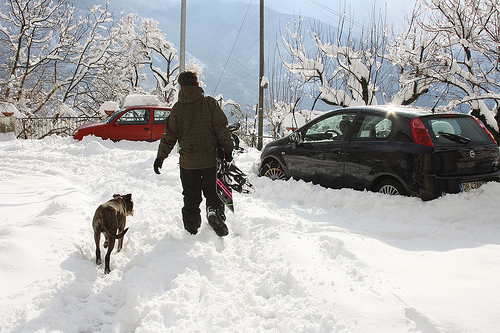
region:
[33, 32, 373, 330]
a person and dog in the snow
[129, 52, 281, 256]
a person holding a snowboard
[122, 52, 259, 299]
a man holding a surfboard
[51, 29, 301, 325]
a man and dog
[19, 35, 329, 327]
a man and dog walking on snow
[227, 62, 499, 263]
a car surround with snow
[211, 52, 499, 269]
snow surrounding a car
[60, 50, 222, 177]
a red car surround in snow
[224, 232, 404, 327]
white snow covering the ground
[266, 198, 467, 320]
snow covering the ground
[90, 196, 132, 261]
back of walking dog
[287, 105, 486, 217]
black car in snow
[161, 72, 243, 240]
man carrying snowboard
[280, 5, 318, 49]
top of mountain on horizon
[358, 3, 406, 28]
blue of daytime sky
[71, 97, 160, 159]
red car in snow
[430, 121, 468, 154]
wiper on back of car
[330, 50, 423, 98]
snow on tree limbs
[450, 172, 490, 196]
license plate on car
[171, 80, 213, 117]
hood on back of coat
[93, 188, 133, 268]
dog walking on snow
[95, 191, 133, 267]
dog has short hair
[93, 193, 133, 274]
dog wagging his tail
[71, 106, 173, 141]
red car parked in snow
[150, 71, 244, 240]
man walking in snow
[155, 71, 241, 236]
man carrying snowboard in snow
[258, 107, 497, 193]
black car parked in snow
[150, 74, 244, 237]
man wearing black pants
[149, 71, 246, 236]
man wearing black boots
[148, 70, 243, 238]
man wearing plaid jacket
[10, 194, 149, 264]
dog waling in the snow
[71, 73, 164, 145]
car has snow on it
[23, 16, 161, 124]
trees are covered in snow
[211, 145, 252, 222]
man is carrying snowboard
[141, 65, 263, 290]
man walking in the snow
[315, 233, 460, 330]
foot prints in the snow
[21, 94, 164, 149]
railing along the road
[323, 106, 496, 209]
car has been cleared of snow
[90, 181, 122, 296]
dog is brown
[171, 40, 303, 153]
two poles by the trees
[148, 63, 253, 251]
A man holding a snowboard.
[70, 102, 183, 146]
A small red car.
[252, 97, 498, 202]
A small black car with a hatchback.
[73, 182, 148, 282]
A dog walking through the snow.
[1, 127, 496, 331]
Snow completely covering the ground.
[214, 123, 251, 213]
A snowboard.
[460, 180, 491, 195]
A license plate on a black car.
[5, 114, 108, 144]
A small fence behind the red car.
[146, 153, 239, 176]
Dark colored gloves.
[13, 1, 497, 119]
An outline of mountains.